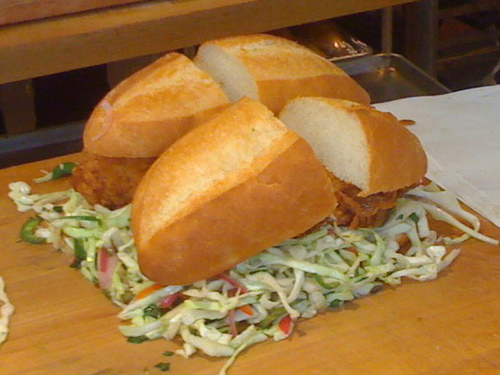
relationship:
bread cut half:
[107, 42, 399, 252] [193, 41, 358, 203]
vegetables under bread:
[181, 251, 458, 284] [107, 42, 399, 252]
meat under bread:
[51, 145, 132, 232] [107, 42, 399, 252]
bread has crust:
[107, 42, 399, 252] [107, 53, 190, 131]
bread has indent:
[107, 42, 399, 252] [223, 35, 282, 99]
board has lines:
[14, 158, 82, 340] [337, 318, 434, 363]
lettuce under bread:
[58, 209, 139, 325] [107, 42, 399, 252]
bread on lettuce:
[107, 42, 399, 252] [58, 209, 139, 325]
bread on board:
[107, 42, 399, 252] [14, 158, 82, 340]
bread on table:
[107, 42, 399, 252] [31, 136, 466, 246]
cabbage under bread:
[298, 236, 408, 301] [107, 42, 399, 252]